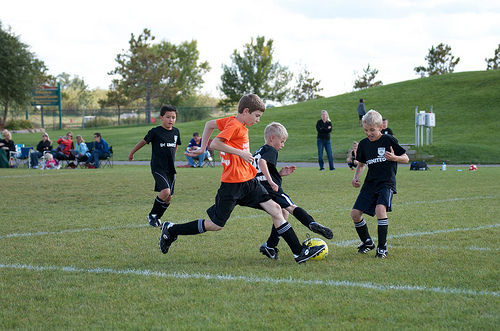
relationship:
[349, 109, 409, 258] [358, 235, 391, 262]
boy wearing black shoes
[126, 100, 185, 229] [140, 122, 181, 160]
boy wearing shirt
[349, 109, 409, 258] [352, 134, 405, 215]
boy in a soccer uniform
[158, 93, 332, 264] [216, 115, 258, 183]
boy wearing orange shirt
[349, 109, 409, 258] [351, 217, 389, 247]
boy wearing socks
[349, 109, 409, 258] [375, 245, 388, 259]
boy wearing a soccer shoe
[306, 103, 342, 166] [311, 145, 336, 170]
person wearing jeans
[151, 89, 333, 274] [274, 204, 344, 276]
boy running for ball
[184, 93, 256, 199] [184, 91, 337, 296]
orange shirt on boy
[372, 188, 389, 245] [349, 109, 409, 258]
leg on boy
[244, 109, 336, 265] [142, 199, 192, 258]
boy wearing shoes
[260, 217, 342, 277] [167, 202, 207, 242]
leg wearing sock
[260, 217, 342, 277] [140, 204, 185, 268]
leg wearing shoe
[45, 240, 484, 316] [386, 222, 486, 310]
line on grass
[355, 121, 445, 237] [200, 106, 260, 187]
boy in shirt